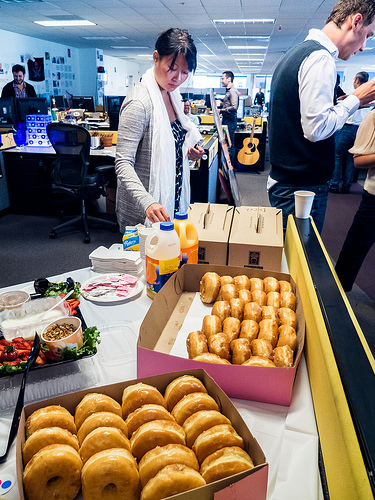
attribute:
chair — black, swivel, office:
[37, 118, 117, 241]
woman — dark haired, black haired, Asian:
[115, 26, 204, 233]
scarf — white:
[137, 65, 201, 227]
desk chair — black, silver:
[27, 106, 121, 243]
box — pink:
[135, 259, 306, 409]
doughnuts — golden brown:
[28, 446, 79, 497]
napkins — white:
[87, 241, 145, 279]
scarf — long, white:
[140, 64, 203, 218]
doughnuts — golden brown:
[196, 272, 220, 298]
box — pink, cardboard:
[13, 367, 270, 499]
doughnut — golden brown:
[22, 443, 79, 499]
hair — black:
[154, 26, 197, 76]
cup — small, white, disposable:
[291, 188, 316, 220]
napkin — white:
[92, 251, 137, 259]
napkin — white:
[91, 260, 116, 266]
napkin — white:
[112, 262, 133, 272]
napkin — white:
[95, 267, 109, 275]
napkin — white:
[112, 265, 142, 275]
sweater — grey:
[113, 82, 158, 234]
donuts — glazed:
[23, 373, 253, 496]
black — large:
[8, 334, 39, 434]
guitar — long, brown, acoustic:
[228, 112, 266, 168]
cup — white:
[291, 185, 317, 220]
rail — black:
[289, 213, 348, 398]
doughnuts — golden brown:
[196, 269, 221, 305]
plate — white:
[80, 271, 142, 304]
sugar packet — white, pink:
[112, 291, 130, 297]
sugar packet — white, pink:
[121, 274, 134, 284]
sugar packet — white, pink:
[91, 290, 100, 295]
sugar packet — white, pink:
[93, 278, 108, 284]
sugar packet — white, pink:
[81, 286, 94, 289]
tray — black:
[0, 277, 96, 377]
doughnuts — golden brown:
[195, 269, 296, 305]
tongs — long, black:
[0, 341, 53, 462]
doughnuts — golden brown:
[12, 365, 278, 497]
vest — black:
[263, 40, 338, 186]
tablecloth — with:
[0, 246, 325, 497]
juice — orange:
[144, 255, 182, 299]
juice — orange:
[172, 219, 199, 265]